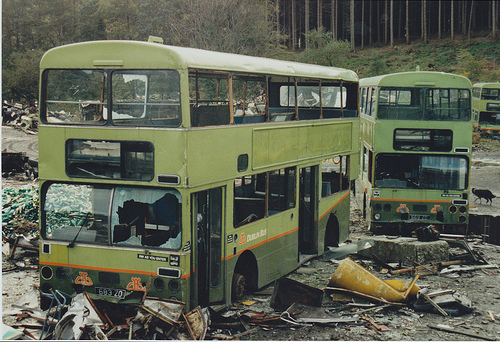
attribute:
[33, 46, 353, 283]
bus — green, old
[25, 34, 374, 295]
busses — old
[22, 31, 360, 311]
busses — not in use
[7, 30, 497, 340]
junk — a lot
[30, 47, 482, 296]
buses — green, abandoned, double decker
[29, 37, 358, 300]
bus — double decker, olive green, abandoned, green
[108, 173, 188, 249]
windows — broken out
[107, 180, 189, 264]
bus window — broken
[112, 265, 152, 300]
bus logo — orange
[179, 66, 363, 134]
windows — in row, broken out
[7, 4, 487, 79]
trees — in background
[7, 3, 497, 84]
plants — in background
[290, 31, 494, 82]
grass — in background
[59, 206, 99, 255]
windshield wiiper — for bus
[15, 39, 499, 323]
buses — double-decker, three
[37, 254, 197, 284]
stripe — orange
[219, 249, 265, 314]
tires — missing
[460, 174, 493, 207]
dog — wandering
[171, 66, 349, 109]
windows — broken